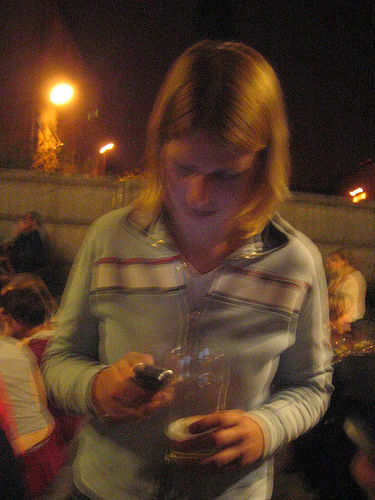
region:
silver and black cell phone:
[123, 358, 177, 392]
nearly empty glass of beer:
[160, 338, 236, 468]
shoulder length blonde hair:
[123, 38, 294, 249]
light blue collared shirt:
[44, 192, 335, 496]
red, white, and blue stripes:
[87, 253, 309, 322]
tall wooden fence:
[3, 159, 373, 278]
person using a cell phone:
[38, 36, 337, 498]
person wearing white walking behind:
[316, 244, 368, 340]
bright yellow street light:
[43, 75, 84, 115]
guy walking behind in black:
[8, 209, 51, 278]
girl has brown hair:
[146, 58, 323, 228]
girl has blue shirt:
[106, 182, 297, 479]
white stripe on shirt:
[73, 249, 324, 358]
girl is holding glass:
[153, 341, 214, 469]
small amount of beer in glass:
[155, 331, 250, 487]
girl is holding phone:
[106, 321, 202, 439]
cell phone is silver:
[130, 351, 177, 419]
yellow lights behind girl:
[47, 69, 124, 166]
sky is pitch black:
[280, 19, 366, 145]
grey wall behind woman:
[8, 167, 111, 251]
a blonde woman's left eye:
[214, 168, 251, 181]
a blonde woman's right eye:
[167, 156, 197, 179]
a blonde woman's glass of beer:
[161, 346, 224, 466]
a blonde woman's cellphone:
[132, 352, 168, 387]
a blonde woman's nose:
[187, 172, 212, 210]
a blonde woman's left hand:
[172, 412, 263, 477]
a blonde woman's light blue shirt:
[43, 210, 333, 498]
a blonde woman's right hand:
[93, 348, 172, 421]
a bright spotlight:
[41, 74, 78, 108]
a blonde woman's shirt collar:
[121, 195, 290, 261]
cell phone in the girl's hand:
[127, 358, 170, 393]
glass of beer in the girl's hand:
[171, 345, 228, 458]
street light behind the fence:
[36, 71, 93, 136]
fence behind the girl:
[35, 169, 104, 214]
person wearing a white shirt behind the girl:
[319, 241, 369, 340]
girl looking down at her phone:
[68, 53, 291, 424]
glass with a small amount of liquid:
[166, 345, 220, 465]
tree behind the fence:
[33, 107, 55, 177]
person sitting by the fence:
[8, 205, 52, 273]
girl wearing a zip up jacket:
[57, 203, 317, 497]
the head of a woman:
[137, 113, 311, 245]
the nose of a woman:
[184, 186, 230, 221]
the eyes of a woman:
[171, 151, 284, 197]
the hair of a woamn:
[114, 70, 335, 223]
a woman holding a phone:
[81, 308, 222, 433]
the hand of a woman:
[83, 309, 220, 439]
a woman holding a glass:
[172, 329, 279, 478]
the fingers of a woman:
[178, 407, 271, 468]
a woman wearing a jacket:
[57, 178, 360, 423]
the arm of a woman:
[32, 196, 176, 426]